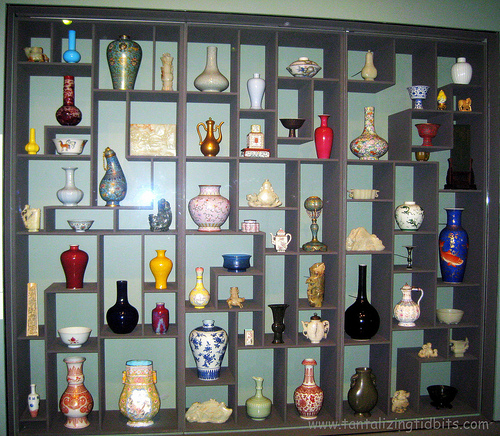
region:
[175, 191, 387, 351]
pottery in the photo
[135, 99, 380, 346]
A cabinet in the photo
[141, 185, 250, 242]
Wall at the back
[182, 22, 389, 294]
Glass cabinet in the photo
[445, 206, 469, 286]
Blue vase in the cabinet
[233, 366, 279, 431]
Green vase in the cabinet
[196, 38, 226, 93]
White vase in the cabinet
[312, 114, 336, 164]
Red vase in the cabinet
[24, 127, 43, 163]
Yellow vase in the cabinet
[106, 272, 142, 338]
Black vase in the cabinet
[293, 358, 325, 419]
A red vase on a stand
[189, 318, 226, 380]
A white and blue vase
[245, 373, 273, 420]
A lime green vase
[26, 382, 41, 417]
A small white vase with red bottom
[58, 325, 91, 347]
A white bowl with a red design on it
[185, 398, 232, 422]
A seashell looking vase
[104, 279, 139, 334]
An all black vase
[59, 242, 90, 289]
A shiny red vase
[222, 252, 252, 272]
A dark blue bowl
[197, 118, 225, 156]
A shiny gold vase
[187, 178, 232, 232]
a vase on a shelf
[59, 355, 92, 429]
a vase on a shelf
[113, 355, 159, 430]
a vase on a shelf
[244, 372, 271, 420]
a vase on a shelf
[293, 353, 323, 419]
a vase on a shelf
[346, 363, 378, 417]
a vase on a shelf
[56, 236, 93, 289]
a vase on a shelf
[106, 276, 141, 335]
a vase on a shelf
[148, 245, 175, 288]
a vase on a shelf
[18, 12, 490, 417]
Many vases and glassware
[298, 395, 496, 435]
Vases available at tantalizingtidbits.com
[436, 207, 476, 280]
Blue vase with fish on it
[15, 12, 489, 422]
Vases on complex shelving unit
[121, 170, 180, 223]
Light shining on the wall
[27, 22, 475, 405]
White wall behind the shelf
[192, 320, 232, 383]
Blue and white vase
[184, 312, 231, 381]
This vase has birds on it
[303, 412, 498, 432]
Text is in white font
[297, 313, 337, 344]
Small teapot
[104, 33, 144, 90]
decorative glass vase on shelf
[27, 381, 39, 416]
tall brown tree trunk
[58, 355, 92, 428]
tall brown tree trunk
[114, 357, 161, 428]
tall brown tree trunk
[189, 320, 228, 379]
tall brown tree trunk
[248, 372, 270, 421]
tall brown tree trunk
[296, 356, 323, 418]
tall brown tree trunk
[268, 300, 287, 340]
tall brown tree trunk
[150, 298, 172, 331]
tall brown tree trunk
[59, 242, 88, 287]
tall brown tree trunk